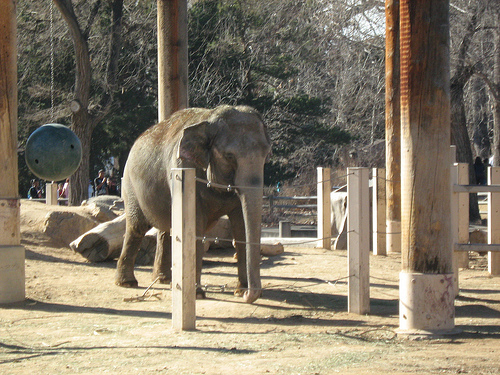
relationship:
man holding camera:
[93, 167, 108, 197] [99, 171, 108, 178]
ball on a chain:
[24, 120, 85, 184] [45, 2, 58, 124]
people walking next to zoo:
[26, 168, 121, 199] [0, 0, 483, 370]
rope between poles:
[195, 174, 347, 315] [166, 162, 374, 330]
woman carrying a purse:
[57, 176, 68, 199] [58, 187, 67, 198]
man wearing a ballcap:
[93, 167, 108, 197] [96, 168, 106, 175]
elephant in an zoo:
[110, 103, 274, 303] [0, 0, 483, 370]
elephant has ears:
[110, 103, 274, 303] [175, 107, 274, 169]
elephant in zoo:
[110, 103, 274, 303] [0, 0, 483, 370]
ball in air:
[24, 120, 85, 184] [26, 103, 132, 217]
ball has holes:
[24, 120, 85, 184] [32, 142, 78, 166]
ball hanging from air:
[24, 120, 85, 184] [11, 1, 112, 121]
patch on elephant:
[140, 102, 270, 149] [110, 103, 274, 303]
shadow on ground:
[1, 295, 400, 327] [1, 205, 499, 373]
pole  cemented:
[396, 0, 456, 339] [395, 330, 456, 340]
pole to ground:
[396, 0, 456, 339] [1, 205, 499, 373]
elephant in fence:
[110, 103, 274, 303] [170, 167, 375, 331]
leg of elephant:
[114, 197, 151, 288] [110, 103, 274, 303]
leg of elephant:
[195, 217, 205, 298] [110, 103, 274, 303]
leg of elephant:
[229, 204, 248, 298] [110, 103, 274, 303]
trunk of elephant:
[235, 163, 265, 303] [110, 103, 274, 303]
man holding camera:
[93, 167, 108, 197] [99, 175, 110, 187]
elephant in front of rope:
[110, 103, 274, 303] [193, 232, 243, 251]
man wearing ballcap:
[93, 167, 108, 197] [96, 168, 106, 175]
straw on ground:
[284, 324, 345, 340] [215, 303, 421, 373]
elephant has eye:
[110, 103, 274, 303] [220, 149, 232, 160]